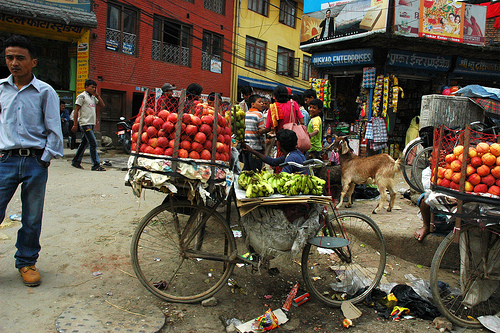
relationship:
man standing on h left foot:
[0, 34, 64, 286] [15, 254, 42, 289]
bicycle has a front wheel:
[132, 147, 387, 307] [301, 212, 387, 306]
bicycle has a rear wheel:
[132, 147, 387, 307] [130, 200, 238, 303]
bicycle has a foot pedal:
[132, 147, 387, 307] [266, 264, 281, 278]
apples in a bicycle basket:
[131, 107, 231, 161] [126, 87, 238, 192]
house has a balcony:
[94, 2, 231, 96] [150, 14, 193, 66]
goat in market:
[330, 138, 404, 215] [1, 1, 500, 333]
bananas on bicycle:
[234, 166, 326, 200] [132, 147, 387, 307]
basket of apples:
[126, 87, 238, 192] [131, 107, 231, 161]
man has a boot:
[0, 34, 64, 286] [15, 254, 42, 289]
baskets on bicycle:
[126, 87, 238, 192] [132, 147, 387, 307]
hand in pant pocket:
[32, 157, 49, 181] [1, 151, 51, 268]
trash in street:
[228, 308, 288, 332] [0, 300, 499, 332]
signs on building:
[303, 1, 389, 44] [308, 32, 496, 100]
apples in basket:
[131, 107, 231, 161] [126, 87, 238, 192]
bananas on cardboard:
[234, 166, 326, 200] [236, 196, 333, 215]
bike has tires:
[132, 147, 387, 307] [130, 200, 238, 303]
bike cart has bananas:
[132, 147, 387, 307] [234, 166, 326, 200]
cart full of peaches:
[431, 120, 499, 202] [431, 142, 499, 196]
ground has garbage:
[0, 300, 499, 332] [380, 284, 434, 321]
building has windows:
[235, 1, 313, 95] [245, 34, 268, 73]